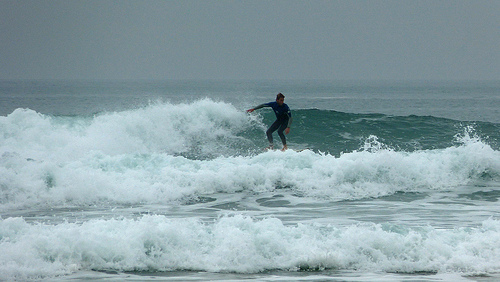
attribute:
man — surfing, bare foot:
[243, 84, 291, 152]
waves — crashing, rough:
[1, 92, 499, 279]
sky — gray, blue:
[1, 1, 497, 84]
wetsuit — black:
[251, 100, 291, 145]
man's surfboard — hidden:
[262, 142, 291, 157]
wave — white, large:
[0, 90, 261, 151]